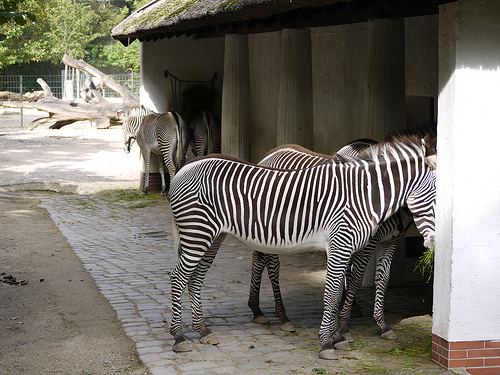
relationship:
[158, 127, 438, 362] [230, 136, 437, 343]
zebra near zebra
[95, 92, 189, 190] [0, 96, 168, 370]
zebra near sidewalk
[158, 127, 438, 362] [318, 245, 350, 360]
zebra has leg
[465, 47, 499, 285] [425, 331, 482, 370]
wall with brick base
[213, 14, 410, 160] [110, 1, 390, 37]
columns under roof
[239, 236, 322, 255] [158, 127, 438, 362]
belly of zebra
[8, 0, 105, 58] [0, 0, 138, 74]
leaves on trees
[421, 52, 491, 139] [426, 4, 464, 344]
shadow on wall edge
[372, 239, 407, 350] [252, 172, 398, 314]
leg of zebra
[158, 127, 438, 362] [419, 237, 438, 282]
zebra eating food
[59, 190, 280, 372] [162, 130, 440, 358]
walkway for zebras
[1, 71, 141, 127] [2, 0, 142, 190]
green fence in background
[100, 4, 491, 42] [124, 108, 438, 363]
roof above zebras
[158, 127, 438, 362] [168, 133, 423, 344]
zebra has stripes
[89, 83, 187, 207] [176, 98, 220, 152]
zebra hidden by shadow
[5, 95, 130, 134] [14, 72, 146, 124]
trunk lie on trunk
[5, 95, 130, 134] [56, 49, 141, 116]
trunk lie on trunk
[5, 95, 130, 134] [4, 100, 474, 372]
trunk lie on ground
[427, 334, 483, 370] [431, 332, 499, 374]
red brick on wall